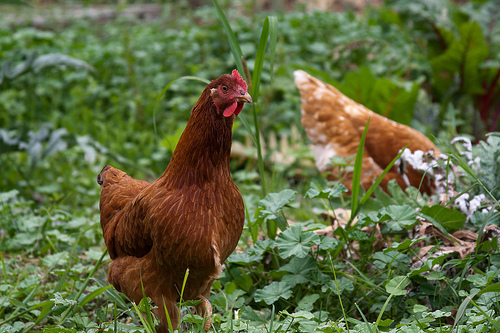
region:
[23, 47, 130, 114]
this is the grass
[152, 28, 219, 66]
the grass is green in color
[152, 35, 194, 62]
the grass is tall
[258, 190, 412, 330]
these are some plants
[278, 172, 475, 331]
the plants are small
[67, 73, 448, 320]
these are two hens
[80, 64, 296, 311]
the hen is standing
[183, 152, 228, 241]
the feathers are brown in color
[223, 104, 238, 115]
the area is red in color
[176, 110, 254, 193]
the neck is short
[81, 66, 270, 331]
chicken is dark brown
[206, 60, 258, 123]
chicken has red on his face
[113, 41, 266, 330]
chicken walking in the grass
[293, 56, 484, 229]
tan and white chicken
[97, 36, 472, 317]
two chickens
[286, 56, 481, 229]
chicken is in the grass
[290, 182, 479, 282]
dead leaves are in the grass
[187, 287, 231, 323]
claw of the chicken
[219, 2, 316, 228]
tall weed in the grass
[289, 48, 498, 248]
chicken's head is in the grass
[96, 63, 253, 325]
this is a hen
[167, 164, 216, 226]
the hen is brown in color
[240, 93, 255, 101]
this is the beak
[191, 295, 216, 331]
this is the leg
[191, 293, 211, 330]
the leg is raised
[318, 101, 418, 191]
the hen is feeding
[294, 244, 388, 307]
these are the leaves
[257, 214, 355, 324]
the leaves are green in color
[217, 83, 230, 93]
this is the eye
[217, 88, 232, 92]
the eye is open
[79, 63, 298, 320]
a rooster walking through a forest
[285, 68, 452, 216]
the wing of a bird raised in the air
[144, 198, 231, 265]
brown feathered breast of the rooster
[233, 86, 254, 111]
red beak of the rooster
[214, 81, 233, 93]
red and black eye of the rooster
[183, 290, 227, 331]
raised foot of the rooster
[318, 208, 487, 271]
dead leaves lying on the plants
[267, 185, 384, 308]
green leafy plants growing on the ground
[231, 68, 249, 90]
red fleshy fin on the rooster's head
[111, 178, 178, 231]
brown feathered wing of the rooster